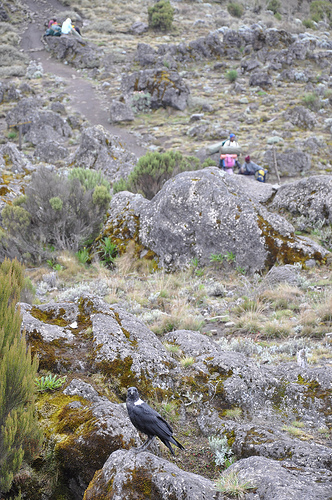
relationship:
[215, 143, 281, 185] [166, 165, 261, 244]
hikers sitting on top of rock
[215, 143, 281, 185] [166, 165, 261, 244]
hikers sitting on rock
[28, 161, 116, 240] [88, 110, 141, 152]
large boulder on a trail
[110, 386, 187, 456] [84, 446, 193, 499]
black bird sitting on rock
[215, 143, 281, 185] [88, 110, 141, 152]
hikers on a trail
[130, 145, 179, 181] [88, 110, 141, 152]
scrub brush on rocky trail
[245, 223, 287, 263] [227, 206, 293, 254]
green moss growing on rocks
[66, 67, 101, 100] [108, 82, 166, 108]
path between rocks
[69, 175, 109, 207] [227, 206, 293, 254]
green bushes growing on rocks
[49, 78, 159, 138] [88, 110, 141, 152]
rock wall on a trail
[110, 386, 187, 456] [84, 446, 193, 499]
black bird on rock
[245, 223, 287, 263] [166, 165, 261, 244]
green moss growing on rock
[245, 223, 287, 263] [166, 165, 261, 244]
green moss growing on top of rock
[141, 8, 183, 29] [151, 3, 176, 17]
tree with green leaves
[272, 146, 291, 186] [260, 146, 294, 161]
brown stick on rock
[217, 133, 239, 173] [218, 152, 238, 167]
hikers wearing pink backpack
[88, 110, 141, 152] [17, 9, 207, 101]
trail dirty on mountianside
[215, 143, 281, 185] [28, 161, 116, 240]
hikers sitting on large boulder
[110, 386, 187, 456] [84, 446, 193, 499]
black bird sitting on top of rock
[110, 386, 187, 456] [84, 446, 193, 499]
black bird standing on rock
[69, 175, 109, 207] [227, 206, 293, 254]
green bushes are beside rocks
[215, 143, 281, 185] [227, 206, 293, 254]
hikers climbing on rocks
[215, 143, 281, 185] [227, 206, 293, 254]
hikers sitting on rocks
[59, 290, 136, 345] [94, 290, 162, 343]
grass becoming dry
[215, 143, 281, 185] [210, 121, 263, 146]
hikers are out of focus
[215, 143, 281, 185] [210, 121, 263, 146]
hikers arent in focus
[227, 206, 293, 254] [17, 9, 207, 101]
rocks together on mountianside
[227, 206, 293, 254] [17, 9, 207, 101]
rocks are same on mountianside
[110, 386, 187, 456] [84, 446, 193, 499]
black bird standing on a rock